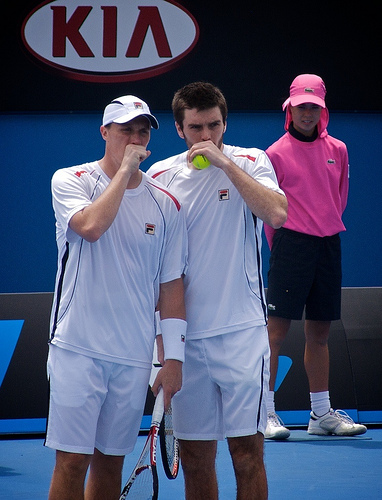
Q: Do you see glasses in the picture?
A: No, there are no glasses.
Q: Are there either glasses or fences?
A: No, there are no glasses or fences.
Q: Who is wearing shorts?
A: The man is wearing shorts.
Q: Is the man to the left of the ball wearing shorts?
A: Yes, the man is wearing shorts.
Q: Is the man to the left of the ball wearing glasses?
A: No, the man is wearing shorts.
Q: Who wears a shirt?
A: The man wears a shirt.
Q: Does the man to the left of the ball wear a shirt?
A: Yes, the man wears a shirt.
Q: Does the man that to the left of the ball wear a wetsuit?
A: No, the man wears a shirt.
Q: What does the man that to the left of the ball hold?
A: The man holds the tennis racket.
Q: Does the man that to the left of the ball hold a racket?
A: Yes, the man holds a racket.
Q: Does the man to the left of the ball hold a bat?
A: No, the man holds a racket.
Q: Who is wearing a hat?
A: The man is wearing a hat.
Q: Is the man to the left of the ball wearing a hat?
A: Yes, the man is wearing a hat.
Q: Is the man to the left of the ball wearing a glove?
A: No, the man is wearing a hat.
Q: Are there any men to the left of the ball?
A: Yes, there is a man to the left of the ball.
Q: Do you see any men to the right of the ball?
A: No, the man is to the left of the ball.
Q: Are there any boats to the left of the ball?
A: No, there is a man to the left of the ball.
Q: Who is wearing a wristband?
A: The man is wearing a wristband.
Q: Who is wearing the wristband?
A: The man is wearing a wristband.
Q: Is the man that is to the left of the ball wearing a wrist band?
A: Yes, the man is wearing a wrist band.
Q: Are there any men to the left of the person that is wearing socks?
A: Yes, there is a man to the left of the person.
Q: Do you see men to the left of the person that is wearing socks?
A: Yes, there is a man to the left of the person.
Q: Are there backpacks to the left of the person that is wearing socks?
A: No, there is a man to the left of the person.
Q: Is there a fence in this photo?
A: No, there are no fences.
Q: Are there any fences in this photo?
A: No, there are no fences.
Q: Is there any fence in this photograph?
A: No, there are no fences.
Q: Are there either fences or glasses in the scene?
A: No, there are no fences or glasses.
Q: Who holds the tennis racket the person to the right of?
A: The man holds the racket.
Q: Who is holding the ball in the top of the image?
A: The man is holding the ball.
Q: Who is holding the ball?
A: The man is holding the ball.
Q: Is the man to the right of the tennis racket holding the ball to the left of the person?
A: Yes, the man is holding the ball.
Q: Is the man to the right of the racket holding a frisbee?
A: No, the man is holding the ball.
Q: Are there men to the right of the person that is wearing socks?
A: No, the man is to the left of the person.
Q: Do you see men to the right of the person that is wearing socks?
A: No, the man is to the left of the person.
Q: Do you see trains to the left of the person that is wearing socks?
A: No, there is a man to the left of the person.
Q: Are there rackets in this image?
A: Yes, there is a racket.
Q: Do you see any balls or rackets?
A: Yes, there is a racket.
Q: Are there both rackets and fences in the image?
A: No, there is a racket but no fences.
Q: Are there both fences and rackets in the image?
A: No, there is a racket but no fences.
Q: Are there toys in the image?
A: No, there are no toys.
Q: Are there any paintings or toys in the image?
A: No, there are no toys or paintings.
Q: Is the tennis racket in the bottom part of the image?
A: Yes, the tennis racket is in the bottom of the image.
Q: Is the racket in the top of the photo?
A: No, the racket is in the bottom of the image.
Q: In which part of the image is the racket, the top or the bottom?
A: The racket is in the bottom of the image.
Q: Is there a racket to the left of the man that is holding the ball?
A: Yes, there is a racket to the left of the man.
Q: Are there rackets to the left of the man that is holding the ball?
A: Yes, there is a racket to the left of the man.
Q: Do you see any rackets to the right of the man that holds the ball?
A: No, the racket is to the left of the man.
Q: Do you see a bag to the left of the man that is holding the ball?
A: No, there is a racket to the left of the man.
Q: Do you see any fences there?
A: No, there are no fences.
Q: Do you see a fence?
A: No, there are no fences.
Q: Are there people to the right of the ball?
A: Yes, there is a person to the right of the ball.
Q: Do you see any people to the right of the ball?
A: Yes, there is a person to the right of the ball.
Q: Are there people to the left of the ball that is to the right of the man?
A: No, the person is to the right of the ball.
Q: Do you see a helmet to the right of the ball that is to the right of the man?
A: No, there is a person to the right of the ball.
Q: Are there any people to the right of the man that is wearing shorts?
A: Yes, there is a person to the right of the man.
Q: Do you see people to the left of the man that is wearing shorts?
A: No, the person is to the right of the man.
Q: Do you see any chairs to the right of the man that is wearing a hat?
A: No, there is a person to the right of the man.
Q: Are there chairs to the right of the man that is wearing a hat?
A: No, there is a person to the right of the man.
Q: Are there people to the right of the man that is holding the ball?
A: Yes, there is a person to the right of the man.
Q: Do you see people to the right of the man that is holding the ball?
A: Yes, there is a person to the right of the man.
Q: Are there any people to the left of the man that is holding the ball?
A: No, the person is to the right of the man.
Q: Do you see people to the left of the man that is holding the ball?
A: No, the person is to the right of the man.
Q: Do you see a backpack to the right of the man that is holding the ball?
A: No, there is a person to the right of the man.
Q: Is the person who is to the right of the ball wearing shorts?
A: Yes, the person is wearing shorts.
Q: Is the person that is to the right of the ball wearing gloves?
A: No, the person is wearing shorts.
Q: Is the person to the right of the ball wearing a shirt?
A: Yes, the person is wearing a shirt.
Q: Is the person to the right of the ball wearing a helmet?
A: No, the person is wearing a shirt.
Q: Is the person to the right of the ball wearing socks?
A: Yes, the person is wearing socks.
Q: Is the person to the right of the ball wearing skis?
A: No, the person is wearing socks.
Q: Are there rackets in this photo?
A: Yes, there is a racket.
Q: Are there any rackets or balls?
A: Yes, there is a racket.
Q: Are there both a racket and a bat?
A: No, there is a racket but no bats.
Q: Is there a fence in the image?
A: No, there are no fences.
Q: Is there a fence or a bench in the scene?
A: No, there are no fences or benches.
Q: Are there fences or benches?
A: No, there are no fences or benches.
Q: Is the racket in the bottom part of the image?
A: Yes, the racket is in the bottom of the image.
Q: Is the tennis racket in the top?
A: No, the tennis racket is in the bottom of the image.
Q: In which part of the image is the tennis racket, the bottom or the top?
A: The tennis racket is in the bottom of the image.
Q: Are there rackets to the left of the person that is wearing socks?
A: Yes, there is a racket to the left of the person.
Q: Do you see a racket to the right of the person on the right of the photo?
A: No, the racket is to the left of the person.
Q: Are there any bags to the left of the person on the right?
A: No, there is a racket to the left of the person.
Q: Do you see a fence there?
A: No, there are no fences.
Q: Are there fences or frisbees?
A: No, there are no fences or frisbees.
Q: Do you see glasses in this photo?
A: No, there are no glasses.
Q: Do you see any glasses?
A: No, there are no glasses.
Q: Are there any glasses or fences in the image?
A: No, there are no glasses or fences.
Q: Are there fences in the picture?
A: No, there are no fences.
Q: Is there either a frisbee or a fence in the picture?
A: No, there are no fences or frisbees.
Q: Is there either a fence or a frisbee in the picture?
A: No, there are no fences or frisbees.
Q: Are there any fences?
A: No, there are no fences.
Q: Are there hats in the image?
A: Yes, there is a hat.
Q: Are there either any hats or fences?
A: Yes, there is a hat.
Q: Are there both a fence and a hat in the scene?
A: No, there is a hat but no fences.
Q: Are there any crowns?
A: No, there are no crowns.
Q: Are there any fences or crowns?
A: No, there are no crowns or fences.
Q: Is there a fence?
A: No, there are no fences.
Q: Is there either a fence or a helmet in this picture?
A: No, there are no fences or helmets.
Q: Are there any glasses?
A: No, there are no glasses.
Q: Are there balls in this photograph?
A: Yes, there is a ball.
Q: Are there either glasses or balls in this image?
A: Yes, there is a ball.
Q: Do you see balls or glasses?
A: Yes, there is a ball.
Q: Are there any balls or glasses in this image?
A: Yes, there is a ball.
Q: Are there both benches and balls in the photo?
A: No, there is a ball but no benches.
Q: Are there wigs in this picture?
A: No, there are no wigs.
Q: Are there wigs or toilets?
A: No, there are no wigs or toilets.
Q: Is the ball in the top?
A: Yes, the ball is in the top of the image.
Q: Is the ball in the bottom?
A: No, the ball is in the top of the image.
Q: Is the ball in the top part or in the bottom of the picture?
A: The ball is in the top of the image.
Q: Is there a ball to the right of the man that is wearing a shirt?
A: Yes, there is a ball to the right of the man.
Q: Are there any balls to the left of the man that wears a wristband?
A: No, the ball is to the right of the man.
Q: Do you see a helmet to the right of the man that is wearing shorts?
A: No, there is a ball to the right of the man.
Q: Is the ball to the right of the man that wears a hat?
A: Yes, the ball is to the right of the man.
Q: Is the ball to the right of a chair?
A: No, the ball is to the right of the man.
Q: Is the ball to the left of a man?
A: No, the ball is to the right of a man.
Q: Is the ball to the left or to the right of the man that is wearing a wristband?
A: The ball is to the right of the man.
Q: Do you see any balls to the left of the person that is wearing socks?
A: Yes, there is a ball to the left of the person.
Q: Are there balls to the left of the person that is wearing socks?
A: Yes, there is a ball to the left of the person.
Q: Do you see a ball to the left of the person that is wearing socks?
A: Yes, there is a ball to the left of the person.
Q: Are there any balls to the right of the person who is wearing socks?
A: No, the ball is to the left of the person.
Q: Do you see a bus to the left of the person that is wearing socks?
A: No, there is a ball to the left of the person.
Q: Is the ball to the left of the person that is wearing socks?
A: Yes, the ball is to the left of the person.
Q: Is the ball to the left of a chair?
A: No, the ball is to the left of the person.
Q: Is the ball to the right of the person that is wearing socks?
A: No, the ball is to the left of the person.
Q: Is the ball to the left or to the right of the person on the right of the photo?
A: The ball is to the left of the person.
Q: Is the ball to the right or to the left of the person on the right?
A: The ball is to the left of the person.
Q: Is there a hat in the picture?
A: Yes, there is a hat.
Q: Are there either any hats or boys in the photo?
A: Yes, there is a hat.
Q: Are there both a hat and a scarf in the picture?
A: No, there is a hat but no scarves.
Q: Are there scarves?
A: No, there are no scarves.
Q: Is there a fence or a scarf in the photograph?
A: No, there are no scarves or fences.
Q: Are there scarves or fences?
A: No, there are no scarves or fences.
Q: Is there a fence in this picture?
A: No, there are no fences.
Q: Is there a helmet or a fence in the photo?
A: No, there are no fences or helmets.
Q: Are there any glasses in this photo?
A: No, there are no glasses.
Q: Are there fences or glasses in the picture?
A: No, there are no glasses or fences.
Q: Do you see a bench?
A: No, there are no benches.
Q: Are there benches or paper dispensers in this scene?
A: No, there are no benches or paper dispensers.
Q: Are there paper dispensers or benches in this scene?
A: No, there are no benches or paper dispensers.